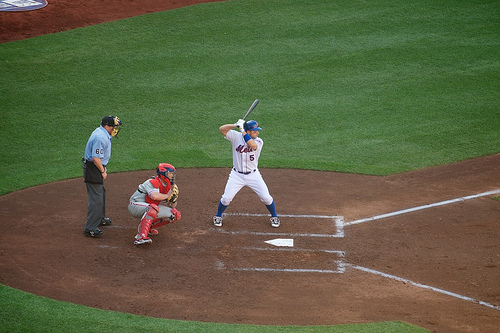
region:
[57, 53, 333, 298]
Three baseball players on the field.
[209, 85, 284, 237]
Batter getting ready to swing at the ball.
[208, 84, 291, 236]
Batter dressed in team uniform.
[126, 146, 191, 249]
Catcher dressed in team uniform.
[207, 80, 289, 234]
Batter holding bat in both hands.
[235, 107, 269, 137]
A blue safety helmet.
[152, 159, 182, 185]
Catcher wearing protective face mask.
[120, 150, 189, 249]
Catcher wearing protective shin guards.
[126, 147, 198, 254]
Catcher with glove on left hand.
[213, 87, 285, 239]
The number 5 on the batter's uniform.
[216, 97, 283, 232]
A man swinging a bat.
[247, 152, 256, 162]
The number five on a jersey.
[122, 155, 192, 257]
Catcher behind the batter.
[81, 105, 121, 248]
Umpire behind the catcher.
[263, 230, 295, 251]
Home plate of a baseball stadium.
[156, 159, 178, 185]
Mask on the catcher's head.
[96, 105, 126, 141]
Mask on the umpire's head.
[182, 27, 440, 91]
Green grass on the field.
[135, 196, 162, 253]
Pads on the catcher's legs.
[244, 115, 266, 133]
Helmet on the batter's head.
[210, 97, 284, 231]
baseball player on a field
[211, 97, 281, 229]
baseball player with a bat in his hand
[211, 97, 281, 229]
baseball player in position to swing his bat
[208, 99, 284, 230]
baseball player at bat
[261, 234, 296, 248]
white base on a field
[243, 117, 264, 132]
blue helmet on a baseball player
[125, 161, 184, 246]
baseball catcher on a field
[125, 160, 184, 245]
baseball catcher dressed in red and gray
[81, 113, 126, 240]
baseball umpire on a field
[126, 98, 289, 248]
two baseball players on a field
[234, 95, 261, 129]
black baseball bat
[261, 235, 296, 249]
white home plate in the dirt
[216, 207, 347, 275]
white lines around the batter's box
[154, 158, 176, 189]
red helmet on the catcher's head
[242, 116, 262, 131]
blue helmet on the batter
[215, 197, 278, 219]
blue socks on the batter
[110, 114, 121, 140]
brown and black face mask on the umpire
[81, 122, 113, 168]
blue shirt on the umpire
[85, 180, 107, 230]
gray shirt on the umpire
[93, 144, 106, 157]
black numbers on the blue shirt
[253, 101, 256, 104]
Bat raised in the air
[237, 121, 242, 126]
Hands in white gloves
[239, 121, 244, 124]
Hands swinging a bat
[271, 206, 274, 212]
A blue sock on the leg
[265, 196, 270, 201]
White trousers around the knee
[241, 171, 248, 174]
A belt around the waist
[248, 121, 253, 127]
Blue head protective gear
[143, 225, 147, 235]
Protective gear for the shin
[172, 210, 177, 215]
Protection on the knee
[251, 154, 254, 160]
Number on the shirt